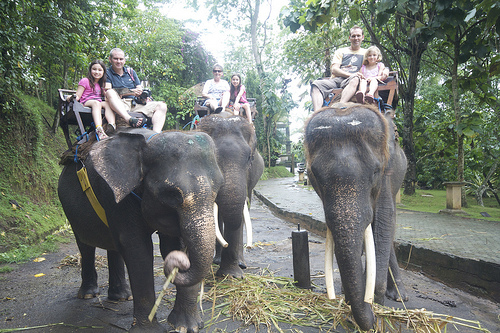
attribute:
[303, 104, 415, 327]
elephant — black, big, large, gray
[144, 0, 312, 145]
sky — bright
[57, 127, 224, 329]
elephant — big, black, large, gray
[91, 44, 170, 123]
person — seated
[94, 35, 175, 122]
person — seated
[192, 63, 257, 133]
person — seated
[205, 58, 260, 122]
person — seated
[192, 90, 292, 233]
elephant — big, black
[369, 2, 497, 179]
trees — green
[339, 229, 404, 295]
tusks — long, white, blunt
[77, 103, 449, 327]
elephants — walking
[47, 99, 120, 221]
bench — slanting, strapped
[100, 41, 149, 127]
adults — smiling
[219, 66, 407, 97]
children — smiling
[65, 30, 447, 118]
people — sitting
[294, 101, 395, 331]
elephant — black, big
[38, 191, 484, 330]
path — paved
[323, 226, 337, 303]
tusk — cut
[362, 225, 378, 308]
tusk — cut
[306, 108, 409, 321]
elephant — big, black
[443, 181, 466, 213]
garbage can — cement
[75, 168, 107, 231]
strap — brown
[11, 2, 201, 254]
trees — green, shady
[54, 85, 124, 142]
seat — wooden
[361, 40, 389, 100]
girl — little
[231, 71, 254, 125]
girl — little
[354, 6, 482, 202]
tree — green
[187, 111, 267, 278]
elephant — large, gray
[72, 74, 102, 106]
shirt — pink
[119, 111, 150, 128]
sandal — black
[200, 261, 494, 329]
weeds — green and yellow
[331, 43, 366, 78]
shirt — yellow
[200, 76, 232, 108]
shirt — white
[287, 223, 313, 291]
pole — small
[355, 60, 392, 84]
shirt — pink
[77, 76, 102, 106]
shirt — pink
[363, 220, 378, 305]
tusk — white, strong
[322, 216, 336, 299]
tusk — white, strong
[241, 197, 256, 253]
tusk — white, strong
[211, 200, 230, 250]
tusk — white, strong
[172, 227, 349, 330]
weeds — green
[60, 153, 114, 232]
strap — yellow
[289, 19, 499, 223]
trees — distant, tall